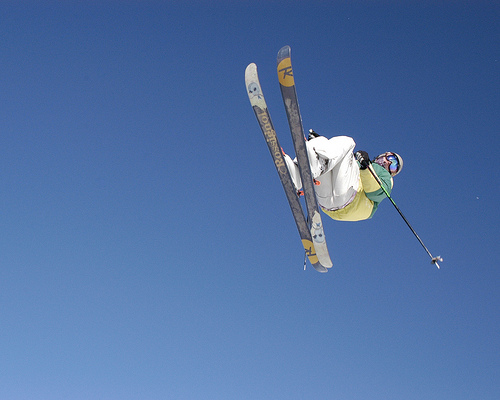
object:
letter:
[279, 66, 293, 79]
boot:
[284, 141, 323, 190]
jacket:
[320, 161, 394, 222]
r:
[305, 247, 317, 257]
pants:
[294, 136, 361, 209]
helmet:
[375, 152, 403, 177]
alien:
[283, 136, 400, 222]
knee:
[337, 135, 356, 150]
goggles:
[387, 155, 398, 173]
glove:
[356, 150, 370, 163]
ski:
[244, 45, 332, 274]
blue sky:
[0, 0, 497, 400]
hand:
[355, 150, 369, 164]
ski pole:
[364, 163, 440, 269]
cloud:
[0, 201, 230, 400]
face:
[376, 155, 399, 172]